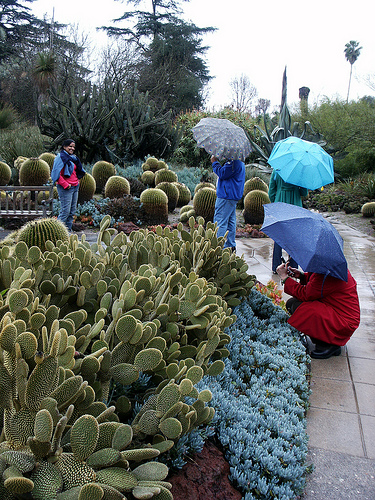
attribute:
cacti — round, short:
[1, 216, 247, 497]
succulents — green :
[201, 279, 317, 498]